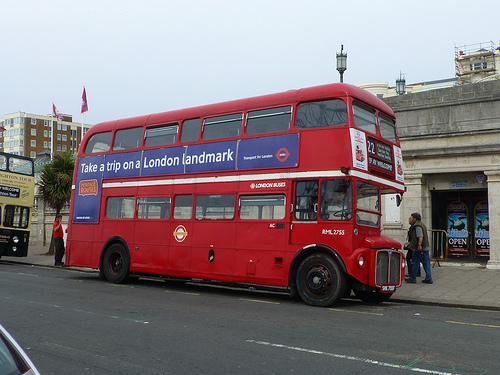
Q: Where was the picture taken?
A: London.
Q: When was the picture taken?
A: Daytime.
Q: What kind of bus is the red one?
A: Double decker.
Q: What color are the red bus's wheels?
A: Black.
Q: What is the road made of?
A: Asphalt.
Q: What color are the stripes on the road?
A: White.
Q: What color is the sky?
A: Blue.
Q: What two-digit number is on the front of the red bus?
A: 22.